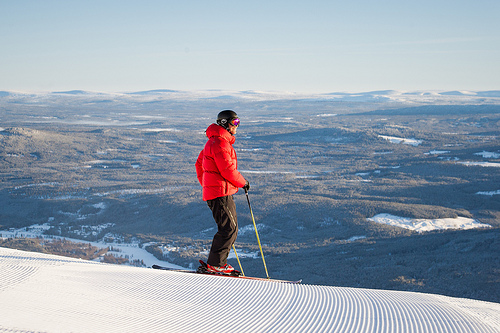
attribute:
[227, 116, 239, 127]
goggles — red, black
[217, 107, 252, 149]
helmet — black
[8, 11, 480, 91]
sky — in the picture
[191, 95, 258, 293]
person — in the picture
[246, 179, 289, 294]
ski rod — yellow 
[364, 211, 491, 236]
patch — large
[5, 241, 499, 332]
snowy hill — in the picture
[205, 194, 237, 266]
pants — black 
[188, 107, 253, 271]
person — in the picture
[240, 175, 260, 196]
glove — black